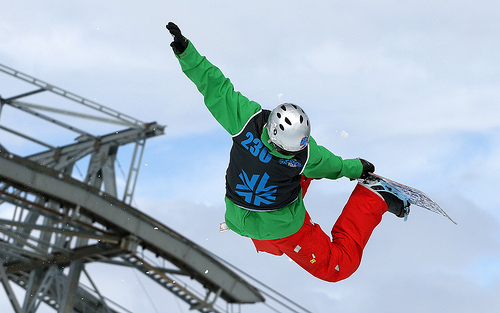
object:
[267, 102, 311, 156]
helmet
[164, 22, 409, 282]
man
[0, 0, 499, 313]
cloudy sky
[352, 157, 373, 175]
hand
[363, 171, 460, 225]
snowboard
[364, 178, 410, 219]
boot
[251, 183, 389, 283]
snow pants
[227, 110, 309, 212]
vest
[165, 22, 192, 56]
glove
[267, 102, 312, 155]
head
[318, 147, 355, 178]
arm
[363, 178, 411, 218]
foot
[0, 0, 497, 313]
cloud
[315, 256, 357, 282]
knee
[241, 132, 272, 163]
number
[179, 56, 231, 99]
arm